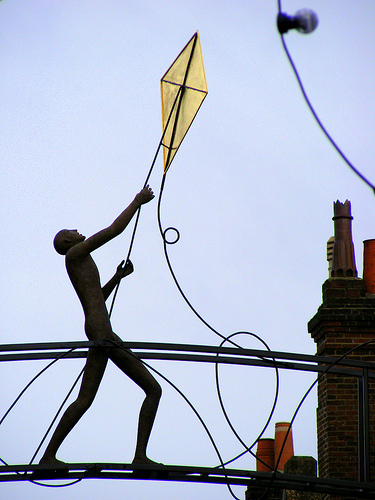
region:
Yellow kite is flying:
[154, 20, 213, 173]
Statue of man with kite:
[36, 191, 164, 477]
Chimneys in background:
[248, 400, 303, 471]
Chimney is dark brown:
[322, 198, 363, 281]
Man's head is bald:
[51, 225, 85, 247]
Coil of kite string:
[186, 295, 281, 444]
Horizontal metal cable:
[2, 331, 314, 389]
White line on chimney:
[272, 424, 292, 433]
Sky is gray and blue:
[22, 194, 277, 453]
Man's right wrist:
[131, 195, 155, 209]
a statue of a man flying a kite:
[11, 39, 373, 421]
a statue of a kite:
[127, 39, 296, 189]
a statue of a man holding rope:
[50, 166, 371, 447]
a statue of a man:
[13, 161, 367, 481]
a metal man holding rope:
[19, 193, 272, 493]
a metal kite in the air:
[26, 21, 291, 332]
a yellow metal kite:
[108, 23, 342, 278]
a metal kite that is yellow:
[107, 24, 289, 210]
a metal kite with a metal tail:
[130, 64, 236, 412]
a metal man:
[16, 173, 291, 488]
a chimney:
[233, 420, 275, 462]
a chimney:
[261, 436, 309, 491]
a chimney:
[257, 388, 342, 483]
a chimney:
[236, 408, 295, 484]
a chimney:
[229, 373, 320, 497]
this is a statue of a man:
[28, 181, 172, 490]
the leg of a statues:
[111, 346, 183, 469]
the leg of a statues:
[34, 349, 102, 460]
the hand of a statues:
[79, 175, 158, 230]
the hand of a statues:
[98, 249, 149, 285]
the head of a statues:
[38, 222, 88, 247]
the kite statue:
[150, 26, 229, 169]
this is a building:
[294, 195, 370, 496]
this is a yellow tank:
[273, 420, 296, 467]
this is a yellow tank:
[254, 430, 278, 485]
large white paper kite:
[130, 18, 228, 322]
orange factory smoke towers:
[242, 400, 307, 492]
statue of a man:
[30, 181, 188, 487]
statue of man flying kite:
[22, 22, 225, 498]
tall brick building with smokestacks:
[297, 184, 374, 487]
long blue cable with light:
[258, 2, 374, 188]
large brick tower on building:
[298, 197, 372, 495]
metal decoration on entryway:
[2, 174, 373, 497]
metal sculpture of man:
[25, 180, 202, 484]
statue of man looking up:
[22, 181, 198, 485]